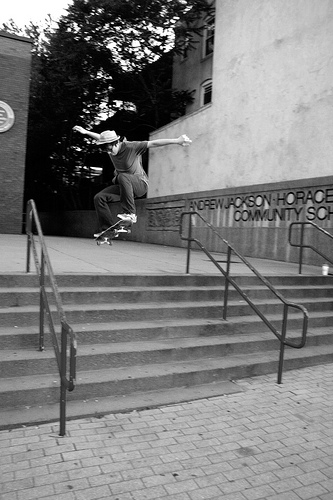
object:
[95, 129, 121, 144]
hat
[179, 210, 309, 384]
rail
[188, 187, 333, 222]
writing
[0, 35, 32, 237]
wall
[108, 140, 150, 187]
shirt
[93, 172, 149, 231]
pants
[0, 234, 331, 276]
stone set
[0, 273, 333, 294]
stairs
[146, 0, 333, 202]
wall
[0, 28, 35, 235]
building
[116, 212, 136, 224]
sneakers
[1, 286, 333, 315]
steps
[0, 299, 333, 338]
steps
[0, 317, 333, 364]
steps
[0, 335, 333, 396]
steps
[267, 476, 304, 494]
brick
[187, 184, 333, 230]
sign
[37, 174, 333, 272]
wall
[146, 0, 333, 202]
building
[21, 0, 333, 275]
community school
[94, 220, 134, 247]
skateboard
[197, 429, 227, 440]
bricks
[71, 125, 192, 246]
boy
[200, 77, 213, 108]
window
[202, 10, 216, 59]
window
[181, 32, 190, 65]
window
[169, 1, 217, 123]
building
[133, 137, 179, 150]
arms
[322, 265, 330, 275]
cup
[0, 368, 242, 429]
step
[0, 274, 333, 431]
stair case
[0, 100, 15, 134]
sign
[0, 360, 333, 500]
sidewalk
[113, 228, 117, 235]
wheels